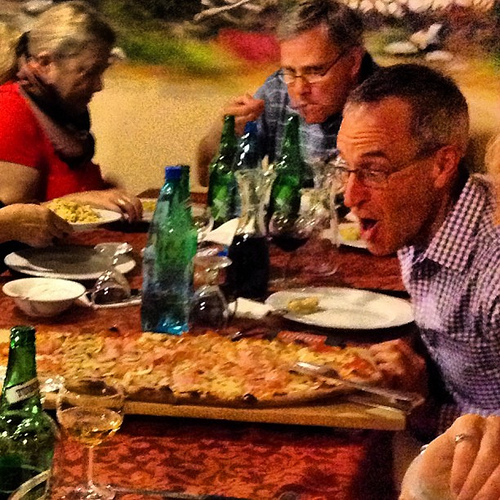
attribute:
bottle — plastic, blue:
[137, 165, 191, 336]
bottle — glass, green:
[208, 113, 238, 223]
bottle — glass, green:
[267, 111, 304, 227]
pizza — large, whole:
[2, 323, 379, 408]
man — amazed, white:
[335, 64, 499, 500]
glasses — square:
[325, 147, 441, 188]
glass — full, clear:
[269, 208, 309, 288]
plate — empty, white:
[266, 284, 417, 332]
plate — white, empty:
[5, 245, 135, 280]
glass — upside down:
[90, 243, 129, 306]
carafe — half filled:
[229, 170, 272, 294]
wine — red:
[228, 233, 267, 300]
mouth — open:
[358, 214, 378, 240]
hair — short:
[342, 62, 472, 156]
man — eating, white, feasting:
[196, 1, 381, 186]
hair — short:
[277, 0, 367, 48]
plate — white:
[140, 198, 203, 217]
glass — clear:
[189, 254, 230, 330]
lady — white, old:
[2, 3, 145, 227]